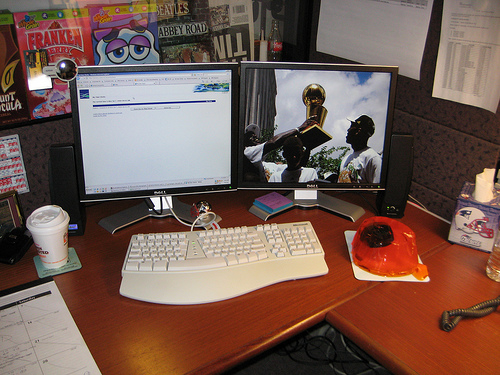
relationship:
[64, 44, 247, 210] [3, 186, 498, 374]
monitor on top of desk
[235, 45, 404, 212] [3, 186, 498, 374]
monitor on top of desk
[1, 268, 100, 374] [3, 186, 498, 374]
calendar on top of desk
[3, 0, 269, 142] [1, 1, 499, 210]
posters are on wall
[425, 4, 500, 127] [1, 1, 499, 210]
paper on wall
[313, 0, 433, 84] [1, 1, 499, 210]
paper on wall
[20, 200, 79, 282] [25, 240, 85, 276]
cup sitting on coaster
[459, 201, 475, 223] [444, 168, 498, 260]
logo on tissue box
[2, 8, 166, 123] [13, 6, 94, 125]
display of box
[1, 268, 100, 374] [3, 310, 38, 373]
calendar has writing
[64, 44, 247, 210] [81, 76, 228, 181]
monitor showing webpage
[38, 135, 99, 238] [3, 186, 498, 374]
speaker on top of desk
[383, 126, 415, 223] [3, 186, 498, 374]
speaker on top of desk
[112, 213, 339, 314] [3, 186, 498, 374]
keyboard on top of desk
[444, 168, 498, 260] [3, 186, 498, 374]
tissue box on top of desk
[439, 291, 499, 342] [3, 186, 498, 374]
cord on top of desk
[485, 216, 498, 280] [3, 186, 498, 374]
bottle on top of desk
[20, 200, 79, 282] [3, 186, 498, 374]
cup on top of desk